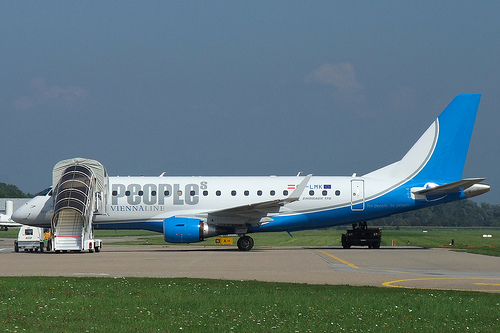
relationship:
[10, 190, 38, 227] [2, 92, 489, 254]
nose of airplane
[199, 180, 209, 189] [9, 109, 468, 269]
big s on airplane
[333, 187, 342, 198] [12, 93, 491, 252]
last window on aircraft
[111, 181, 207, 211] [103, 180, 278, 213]
peoples viennaline on side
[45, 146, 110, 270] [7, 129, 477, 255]
staircase attached to plane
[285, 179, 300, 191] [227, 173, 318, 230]
flag above wings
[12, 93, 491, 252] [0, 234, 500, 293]
aircraft parked on ground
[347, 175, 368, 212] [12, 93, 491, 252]
door on aircraft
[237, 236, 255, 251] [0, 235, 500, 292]
gear on ground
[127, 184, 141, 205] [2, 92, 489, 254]
e on airplane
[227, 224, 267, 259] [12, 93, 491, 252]
gear underneath aircraft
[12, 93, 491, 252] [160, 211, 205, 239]
aircraft has engine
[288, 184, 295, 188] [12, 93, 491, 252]
flag painted on aircraft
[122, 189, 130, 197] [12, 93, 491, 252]
window on aircraft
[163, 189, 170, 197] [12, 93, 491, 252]
window on aircraft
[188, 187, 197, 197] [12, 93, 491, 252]
window on aircraft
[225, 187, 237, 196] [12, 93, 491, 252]
window on aircraft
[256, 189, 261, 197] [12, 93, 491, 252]
window on aircraft